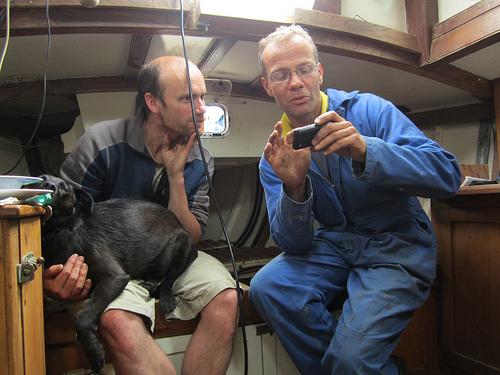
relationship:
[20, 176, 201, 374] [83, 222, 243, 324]
lab sitting in lap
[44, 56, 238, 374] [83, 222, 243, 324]
man has lap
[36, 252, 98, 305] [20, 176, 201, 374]
hand holding lab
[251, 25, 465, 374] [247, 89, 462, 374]
man wearing overalls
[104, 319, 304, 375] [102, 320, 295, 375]
cabinets are for storage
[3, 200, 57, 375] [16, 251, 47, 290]
cabinet has lock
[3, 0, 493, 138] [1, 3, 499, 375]
frame inside boat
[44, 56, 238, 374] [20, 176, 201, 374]
man holding lab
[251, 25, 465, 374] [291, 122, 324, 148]
man using a cellphone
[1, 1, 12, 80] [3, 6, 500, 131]
cord hanging rom ceiling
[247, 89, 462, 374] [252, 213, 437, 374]
overalls has trouser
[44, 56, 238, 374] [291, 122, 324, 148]
man looking at cellphone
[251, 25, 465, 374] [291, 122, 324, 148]
man looking at cellphone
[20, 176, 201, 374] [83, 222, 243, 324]
lab slying on lap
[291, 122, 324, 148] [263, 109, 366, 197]
cellphone on both hands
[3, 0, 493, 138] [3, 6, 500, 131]
wooden on ceiling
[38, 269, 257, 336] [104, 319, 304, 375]
bench on top of cabinets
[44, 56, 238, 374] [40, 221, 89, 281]
man holding up chin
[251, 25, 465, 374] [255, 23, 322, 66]
man has wide forehead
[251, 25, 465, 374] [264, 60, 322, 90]
man wearing eyeglasses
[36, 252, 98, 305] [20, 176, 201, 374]
hand over lab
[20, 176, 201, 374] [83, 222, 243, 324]
lab on lap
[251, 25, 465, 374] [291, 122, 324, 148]
man holding cellphone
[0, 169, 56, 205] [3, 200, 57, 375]
dishes are on top of cabinet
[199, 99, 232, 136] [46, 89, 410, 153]
window on wall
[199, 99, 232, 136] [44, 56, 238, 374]
window behind man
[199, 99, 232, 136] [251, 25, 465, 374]
window behind man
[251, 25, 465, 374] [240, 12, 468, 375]
man in right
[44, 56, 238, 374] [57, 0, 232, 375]
man on left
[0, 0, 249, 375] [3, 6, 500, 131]
wires are hanging from ceiling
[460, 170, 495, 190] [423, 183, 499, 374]
papers are laying on cabinet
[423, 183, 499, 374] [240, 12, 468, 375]
cabinet in right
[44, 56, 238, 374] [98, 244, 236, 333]
man wearing shorts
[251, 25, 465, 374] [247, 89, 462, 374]
man dressed blue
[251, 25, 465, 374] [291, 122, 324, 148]
man looking at h cellphone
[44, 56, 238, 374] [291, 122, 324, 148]
man looking cellphone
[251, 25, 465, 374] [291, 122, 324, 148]
man looking cellphone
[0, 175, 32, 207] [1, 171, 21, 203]
cup above cupboard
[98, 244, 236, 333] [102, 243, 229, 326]
shorts are colour cream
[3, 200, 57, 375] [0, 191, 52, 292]
cabinet has colors